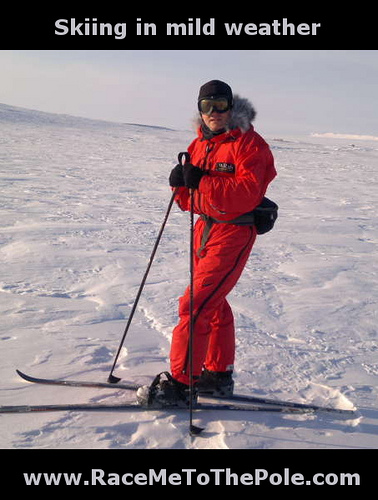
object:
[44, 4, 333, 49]
sign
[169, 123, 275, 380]
outfit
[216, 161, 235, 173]
emblem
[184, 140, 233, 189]
chest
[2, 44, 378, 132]
sky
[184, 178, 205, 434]
ski pole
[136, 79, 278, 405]
skier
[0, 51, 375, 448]
photo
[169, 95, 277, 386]
snowsuit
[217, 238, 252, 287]
stripe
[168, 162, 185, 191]
right hand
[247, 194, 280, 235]
bag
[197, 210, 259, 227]
waist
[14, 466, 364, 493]
www address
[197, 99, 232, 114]
goggles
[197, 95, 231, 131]
guys face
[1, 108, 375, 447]
snow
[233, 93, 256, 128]
fur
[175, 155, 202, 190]
left hand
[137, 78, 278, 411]
man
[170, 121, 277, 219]
coat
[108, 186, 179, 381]
ski pole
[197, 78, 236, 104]
hat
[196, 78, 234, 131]
head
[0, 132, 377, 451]
ground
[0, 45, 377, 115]
cloud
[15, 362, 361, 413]
ski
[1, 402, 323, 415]
ski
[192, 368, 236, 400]
shoe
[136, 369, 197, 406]
shoe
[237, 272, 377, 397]
track